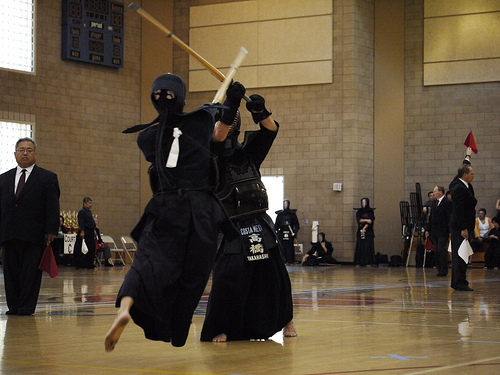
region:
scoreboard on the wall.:
[82, 28, 113, 51]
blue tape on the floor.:
[372, 350, 422, 364]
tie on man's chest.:
[12, 168, 28, 199]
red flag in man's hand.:
[463, 130, 480, 151]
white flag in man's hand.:
[77, 238, 86, 259]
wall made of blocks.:
[305, 108, 330, 147]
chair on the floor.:
[117, 236, 135, 256]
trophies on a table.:
[63, 209, 76, 228]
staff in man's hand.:
[147, 12, 205, 59]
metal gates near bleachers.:
[405, 184, 420, 220]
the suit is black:
[3, 166, 78, 322]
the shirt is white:
[12, 167, 34, 185]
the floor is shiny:
[361, 285, 465, 373]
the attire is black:
[131, 119, 226, 306]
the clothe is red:
[457, 130, 487, 160]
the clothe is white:
[456, 239, 477, 269]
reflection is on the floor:
[456, 294, 499, 331]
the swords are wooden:
[198, 55, 256, 97]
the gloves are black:
[139, 84, 226, 372]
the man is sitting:
[310, 225, 335, 267]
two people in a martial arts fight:
[89, 0, 332, 362]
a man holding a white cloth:
[446, 156, 477, 290]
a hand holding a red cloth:
[457, 130, 479, 162]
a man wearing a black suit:
[7, 136, 69, 315]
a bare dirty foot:
[102, 310, 132, 355]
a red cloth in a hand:
[40, 245, 60, 272]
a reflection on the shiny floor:
[460, 300, 498, 347]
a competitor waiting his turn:
[349, 192, 384, 268]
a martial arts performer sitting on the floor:
[298, 232, 336, 264]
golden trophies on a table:
[58, 208, 78, 233]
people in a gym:
[1, 0, 498, 372]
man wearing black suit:
[2, 123, 68, 323]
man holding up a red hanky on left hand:
[431, 122, 490, 297]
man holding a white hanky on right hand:
[437, 160, 487, 299]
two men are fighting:
[80, 5, 330, 355]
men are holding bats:
[75, 0, 310, 345]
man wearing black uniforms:
[85, 40, 315, 350]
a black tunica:
[115, 105, 225, 345]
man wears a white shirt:
[5, 126, 65, 321]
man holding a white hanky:
[70, 190, 106, 272]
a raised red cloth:
[462, 127, 477, 154]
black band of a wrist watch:
[463, 148, 475, 163]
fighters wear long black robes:
[123, 115, 298, 340]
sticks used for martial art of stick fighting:
[162, 37, 267, 118]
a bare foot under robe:
[97, 298, 139, 357]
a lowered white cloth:
[451, 230, 482, 265]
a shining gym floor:
[6, 243, 499, 373]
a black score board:
[59, 0, 124, 74]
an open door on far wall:
[258, 167, 294, 217]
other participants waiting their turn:
[273, 197, 377, 267]